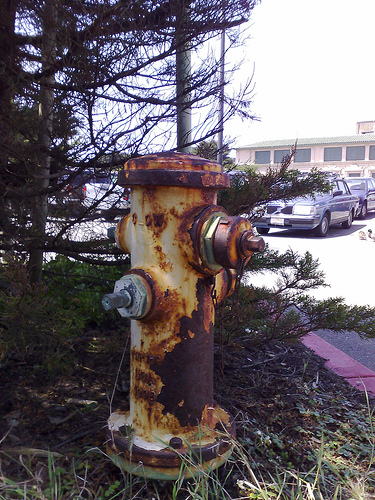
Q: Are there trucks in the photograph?
A: No, there are no trucks.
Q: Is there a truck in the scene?
A: No, there are no trucks.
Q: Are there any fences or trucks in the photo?
A: No, there are no trucks or fences.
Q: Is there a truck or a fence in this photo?
A: No, there are no trucks or fences.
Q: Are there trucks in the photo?
A: No, there are no trucks.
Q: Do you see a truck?
A: No, there are no trucks.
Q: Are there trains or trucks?
A: No, there are no trucks or trains.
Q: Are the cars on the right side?
A: Yes, the cars are on the right of the image.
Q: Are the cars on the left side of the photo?
A: No, the cars are on the right of the image.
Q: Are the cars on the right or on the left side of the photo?
A: The cars are on the right of the image.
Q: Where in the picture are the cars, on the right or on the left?
A: The cars are on the right of the image.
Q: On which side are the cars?
A: The cars are on the right of the image.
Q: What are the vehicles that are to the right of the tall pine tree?
A: The vehicles are cars.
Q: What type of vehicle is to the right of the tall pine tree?
A: The vehicles are cars.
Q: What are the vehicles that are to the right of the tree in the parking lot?
A: The vehicles are cars.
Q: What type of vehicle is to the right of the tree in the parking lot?
A: The vehicles are cars.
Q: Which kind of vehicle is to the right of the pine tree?
A: The vehicles are cars.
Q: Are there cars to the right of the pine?
A: Yes, there are cars to the right of the pine.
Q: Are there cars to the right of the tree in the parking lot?
A: Yes, there are cars to the right of the pine.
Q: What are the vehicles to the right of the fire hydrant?
A: The vehicles are cars.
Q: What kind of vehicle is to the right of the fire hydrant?
A: The vehicles are cars.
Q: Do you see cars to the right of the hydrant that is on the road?
A: Yes, there are cars to the right of the fire hydrant.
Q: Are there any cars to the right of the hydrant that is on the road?
A: Yes, there are cars to the right of the fire hydrant.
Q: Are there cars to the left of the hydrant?
A: No, the cars are to the right of the hydrant.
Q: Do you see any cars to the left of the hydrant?
A: No, the cars are to the right of the hydrant.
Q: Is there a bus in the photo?
A: No, there are no buses.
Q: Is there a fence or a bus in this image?
A: No, there are no buses or fences.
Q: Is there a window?
A: Yes, there is a window.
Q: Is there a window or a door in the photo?
A: Yes, there is a window.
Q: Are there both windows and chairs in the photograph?
A: No, there is a window but no chairs.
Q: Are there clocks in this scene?
A: No, there are no clocks.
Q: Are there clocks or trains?
A: No, there are no clocks or trains.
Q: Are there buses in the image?
A: No, there are no buses.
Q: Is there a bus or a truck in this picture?
A: No, there are no buses or trucks.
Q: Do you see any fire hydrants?
A: Yes, there is a fire hydrant.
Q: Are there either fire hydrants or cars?
A: Yes, there is a fire hydrant.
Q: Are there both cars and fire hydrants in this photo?
A: Yes, there are both a fire hydrant and a car.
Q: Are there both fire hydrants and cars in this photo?
A: Yes, there are both a fire hydrant and a car.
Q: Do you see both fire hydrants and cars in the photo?
A: Yes, there are both a fire hydrant and a car.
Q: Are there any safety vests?
A: No, there are no safety vests.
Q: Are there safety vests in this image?
A: No, there are no safety vests.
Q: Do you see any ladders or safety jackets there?
A: No, there are no safety jackets or ladders.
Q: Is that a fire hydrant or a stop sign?
A: That is a fire hydrant.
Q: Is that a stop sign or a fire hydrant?
A: That is a fire hydrant.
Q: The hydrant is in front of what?
A: The hydrant is in front of the trees.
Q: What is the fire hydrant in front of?
A: The hydrant is in front of the trees.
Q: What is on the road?
A: The hydrant is on the road.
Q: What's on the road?
A: The hydrant is on the road.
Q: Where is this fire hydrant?
A: The fire hydrant is on the road.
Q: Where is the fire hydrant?
A: The fire hydrant is on the road.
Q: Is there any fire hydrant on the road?
A: Yes, there is a fire hydrant on the road.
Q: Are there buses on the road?
A: No, there is a fire hydrant on the road.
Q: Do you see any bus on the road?
A: No, there is a fire hydrant on the road.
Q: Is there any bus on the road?
A: No, there is a fire hydrant on the road.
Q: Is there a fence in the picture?
A: No, there are no fences.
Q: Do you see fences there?
A: No, there are no fences.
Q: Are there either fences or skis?
A: No, there are no fences or skis.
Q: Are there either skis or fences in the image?
A: No, there are no fences or skis.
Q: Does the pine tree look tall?
A: Yes, the pine tree is tall.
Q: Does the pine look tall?
A: Yes, the pine is tall.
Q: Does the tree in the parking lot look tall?
A: Yes, the pine is tall.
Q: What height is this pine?
A: The pine is tall.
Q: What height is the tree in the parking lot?
A: The pine is tall.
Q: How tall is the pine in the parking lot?
A: The pine tree is tall.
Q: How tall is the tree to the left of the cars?
A: The pine tree is tall.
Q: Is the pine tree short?
A: No, the pine tree is tall.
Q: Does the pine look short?
A: No, the pine is tall.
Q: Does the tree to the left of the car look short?
A: No, the pine is tall.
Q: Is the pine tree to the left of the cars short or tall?
A: The pine tree is tall.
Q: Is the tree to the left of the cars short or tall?
A: The pine tree is tall.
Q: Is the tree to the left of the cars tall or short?
A: The pine tree is tall.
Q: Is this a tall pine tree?
A: Yes, this is a tall pine tree.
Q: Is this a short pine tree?
A: No, this is a tall pine tree.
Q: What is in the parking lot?
A: The pine is in the parking lot.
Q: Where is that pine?
A: The pine is in the parking lot.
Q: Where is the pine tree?
A: The pine is in the parking lot.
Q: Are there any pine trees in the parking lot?
A: Yes, there is a pine tree in the parking lot.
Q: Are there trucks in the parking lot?
A: No, there is a pine tree in the parking lot.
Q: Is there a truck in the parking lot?
A: No, there is a pine tree in the parking lot.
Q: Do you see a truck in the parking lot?
A: No, there is a pine tree in the parking lot.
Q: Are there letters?
A: Yes, there are letters.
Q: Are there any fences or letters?
A: Yes, there are letters.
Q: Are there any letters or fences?
A: Yes, there are letters.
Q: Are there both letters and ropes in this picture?
A: No, there are letters but no ropes.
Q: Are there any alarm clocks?
A: No, there are no alarm clocks.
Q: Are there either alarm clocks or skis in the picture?
A: No, there are no alarm clocks or skis.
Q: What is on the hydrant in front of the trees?
A: The letters are on the hydrant.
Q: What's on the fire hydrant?
A: The letters are on the hydrant.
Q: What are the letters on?
A: The letters are on the fire hydrant.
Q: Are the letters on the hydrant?
A: Yes, the letters are on the hydrant.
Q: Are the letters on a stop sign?
A: No, the letters are on the hydrant.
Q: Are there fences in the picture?
A: No, there are no fences.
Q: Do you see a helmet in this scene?
A: No, there are no helmets.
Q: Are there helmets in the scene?
A: No, there are no helmets.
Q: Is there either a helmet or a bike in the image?
A: No, there are no helmets or bikes.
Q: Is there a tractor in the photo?
A: No, there are no tractors.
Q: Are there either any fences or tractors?
A: No, there are no tractors or fences.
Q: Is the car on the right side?
A: Yes, the car is on the right of the image.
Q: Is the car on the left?
A: No, the car is on the right of the image.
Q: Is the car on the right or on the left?
A: The car is on the right of the image.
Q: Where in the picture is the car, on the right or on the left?
A: The car is on the right of the image.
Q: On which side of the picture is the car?
A: The car is on the right of the image.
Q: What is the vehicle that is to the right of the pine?
A: The vehicle is a car.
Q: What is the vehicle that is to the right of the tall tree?
A: The vehicle is a car.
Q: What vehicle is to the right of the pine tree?
A: The vehicle is a car.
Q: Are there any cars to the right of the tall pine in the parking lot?
A: Yes, there is a car to the right of the pine.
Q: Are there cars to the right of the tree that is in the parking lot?
A: Yes, there is a car to the right of the pine.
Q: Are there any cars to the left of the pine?
A: No, the car is to the right of the pine.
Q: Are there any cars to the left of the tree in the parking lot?
A: No, the car is to the right of the pine.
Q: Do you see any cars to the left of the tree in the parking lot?
A: No, the car is to the right of the pine.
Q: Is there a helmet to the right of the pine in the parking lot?
A: No, there is a car to the right of the pine tree.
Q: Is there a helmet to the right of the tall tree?
A: No, there is a car to the right of the pine tree.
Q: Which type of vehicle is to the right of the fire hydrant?
A: The vehicle is a car.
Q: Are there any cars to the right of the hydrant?
A: Yes, there is a car to the right of the hydrant.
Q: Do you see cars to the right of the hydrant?
A: Yes, there is a car to the right of the hydrant.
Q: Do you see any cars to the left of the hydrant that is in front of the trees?
A: No, the car is to the right of the fire hydrant.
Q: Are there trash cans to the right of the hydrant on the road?
A: No, there is a car to the right of the fire hydrant.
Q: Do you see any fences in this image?
A: No, there are no fences.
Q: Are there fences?
A: No, there are no fences.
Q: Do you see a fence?
A: No, there are no fences.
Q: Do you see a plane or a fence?
A: No, there are no fences or airplanes.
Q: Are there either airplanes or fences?
A: No, there are no fences or airplanes.